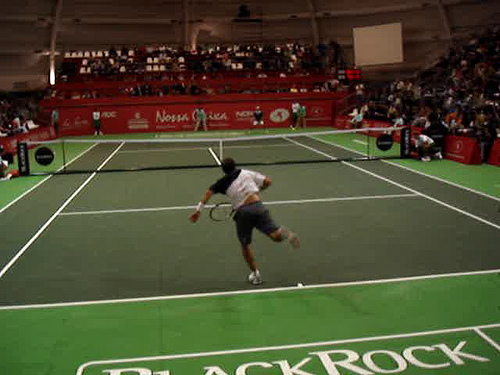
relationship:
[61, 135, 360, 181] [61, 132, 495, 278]
net on court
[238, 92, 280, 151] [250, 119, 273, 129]
player wears shorts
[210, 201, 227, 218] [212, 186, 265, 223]
head on racket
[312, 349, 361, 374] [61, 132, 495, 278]
r on court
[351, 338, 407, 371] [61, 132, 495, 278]
o on court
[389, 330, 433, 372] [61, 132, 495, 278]
c on court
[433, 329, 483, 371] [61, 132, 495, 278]
k on court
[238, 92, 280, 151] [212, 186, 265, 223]
player has racket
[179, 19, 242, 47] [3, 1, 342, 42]
shadow on wall